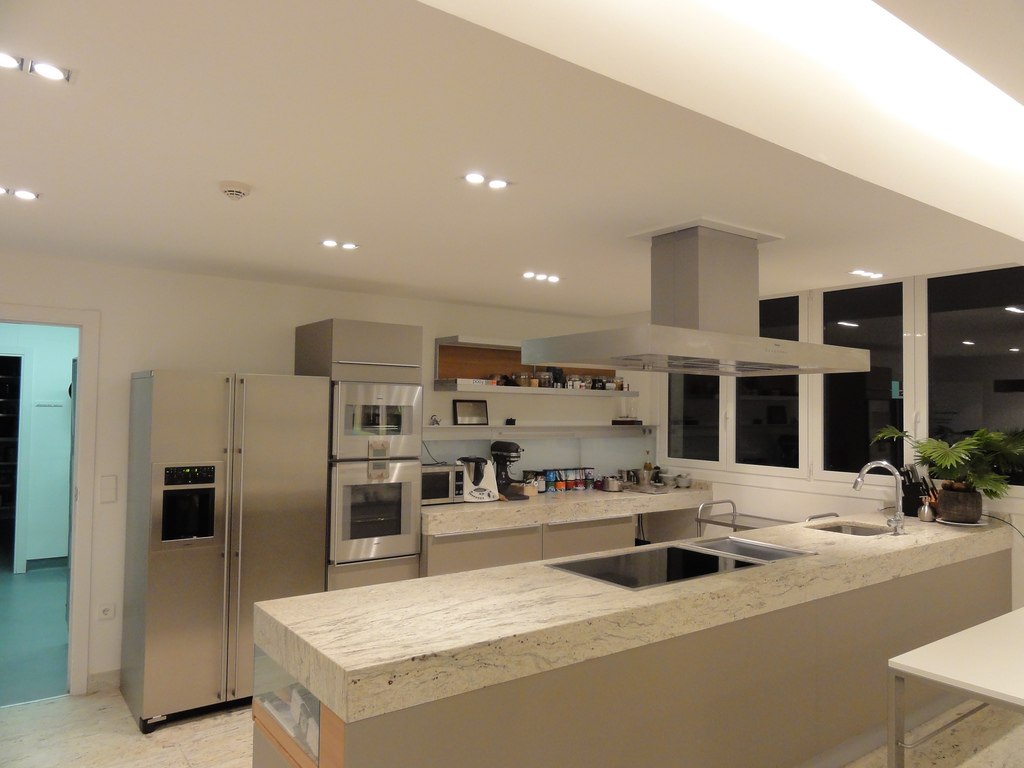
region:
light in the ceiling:
[497, 247, 578, 296]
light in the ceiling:
[292, 207, 382, 269]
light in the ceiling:
[4, 30, 80, 100]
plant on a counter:
[915, 409, 995, 534]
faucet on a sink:
[839, 449, 913, 549]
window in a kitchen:
[928, 286, 1015, 417]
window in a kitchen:
[725, 375, 793, 478]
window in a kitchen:
[648, 371, 726, 457]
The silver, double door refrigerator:
[116, 361, 335, 734]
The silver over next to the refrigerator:
[329, 382, 424, 582]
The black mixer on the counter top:
[477, 425, 538, 502]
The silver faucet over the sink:
[849, 452, 917, 541]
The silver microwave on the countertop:
[413, 462, 470, 508]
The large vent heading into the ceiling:
[506, 203, 881, 401]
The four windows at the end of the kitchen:
[657, 256, 1021, 488]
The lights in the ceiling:
[0, 47, 886, 300]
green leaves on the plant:
[918, 434, 961, 472]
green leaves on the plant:
[868, 408, 903, 460]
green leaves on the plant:
[889, 440, 956, 475]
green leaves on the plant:
[927, 437, 997, 472]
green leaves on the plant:
[942, 420, 1020, 472]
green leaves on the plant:
[996, 419, 1012, 458]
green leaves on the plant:
[886, 373, 959, 472]